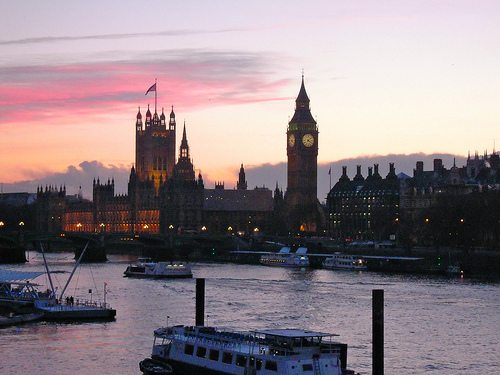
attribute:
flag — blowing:
[145, 82, 155, 95]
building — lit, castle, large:
[128, 77, 177, 201]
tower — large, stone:
[286, 68, 318, 207]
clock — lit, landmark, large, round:
[303, 132, 316, 146]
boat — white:
[124, 256, 193, 279]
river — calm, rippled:
[2, 246, 500, 373]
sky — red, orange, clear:
[1, 2, 499, 199]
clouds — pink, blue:
[1, 25, 468, 203]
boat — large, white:
[132, 280, 383, 375]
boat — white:
[322, 254, 367, 272]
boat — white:
[262, 251, 310, 268]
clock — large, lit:
[288, 135, 296, 145]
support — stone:
[75, 238, 109, 262]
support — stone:
[1, 250, 29, 264]